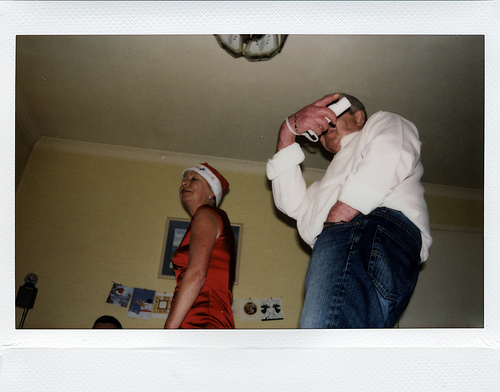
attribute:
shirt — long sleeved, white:
[262, 110, 432, 261]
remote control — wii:
[288, 91, 343, 137]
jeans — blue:
[296, 206, 422, 327]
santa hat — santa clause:
[178, 159, 230, 206]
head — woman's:
[168, 147, 256, 212]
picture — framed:
[153, 207, 248, 287]